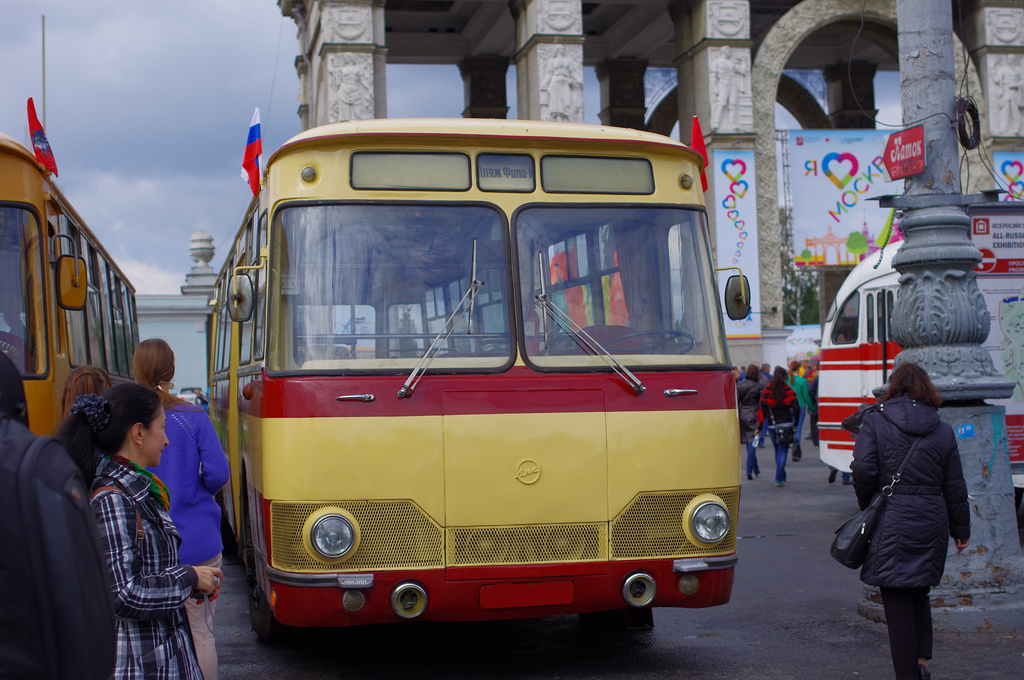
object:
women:
[50, 385, 226, 677]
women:
[826, 360, 974, 679]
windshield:
[514, 204, 722, 359]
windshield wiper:
[395, 237, 486, 397]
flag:
[239, 106, 266, 198]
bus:
[195, 116, 745, 638]